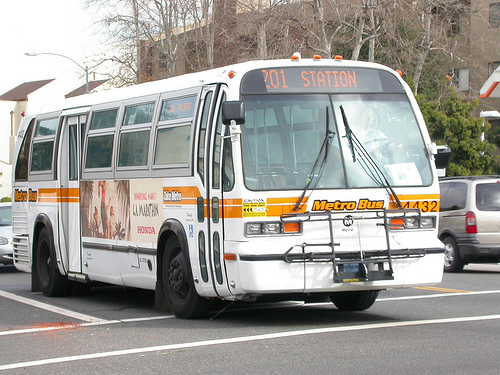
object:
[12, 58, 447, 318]
bus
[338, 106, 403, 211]
windshield wipers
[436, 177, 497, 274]
van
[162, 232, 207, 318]
tire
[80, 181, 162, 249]
advertisement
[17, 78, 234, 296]
side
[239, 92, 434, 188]
windshield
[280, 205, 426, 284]
bike rack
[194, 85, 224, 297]
door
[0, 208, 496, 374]
street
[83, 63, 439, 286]
bus frame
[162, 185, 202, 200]
stripe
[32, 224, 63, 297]
wheel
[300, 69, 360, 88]
station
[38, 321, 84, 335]
spill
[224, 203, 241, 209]
lines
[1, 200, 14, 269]
car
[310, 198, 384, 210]
logo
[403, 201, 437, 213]
numbering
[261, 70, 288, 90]
number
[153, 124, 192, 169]
windows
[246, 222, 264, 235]
headlights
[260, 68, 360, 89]
201 station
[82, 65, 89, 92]
light pole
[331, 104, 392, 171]
bus driver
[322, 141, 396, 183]
seat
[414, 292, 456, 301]
line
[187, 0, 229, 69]
trees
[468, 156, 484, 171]
leaves